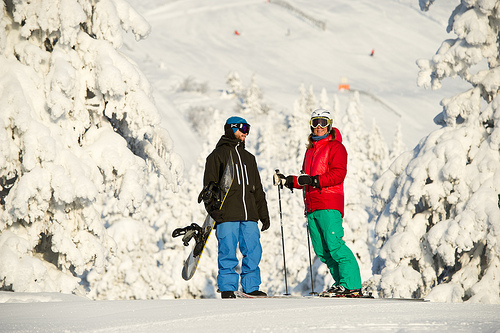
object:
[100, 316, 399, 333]
snow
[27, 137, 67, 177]
snow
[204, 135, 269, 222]
sweater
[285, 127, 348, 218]
coat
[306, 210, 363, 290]
pants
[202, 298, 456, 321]
snow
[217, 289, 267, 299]
boots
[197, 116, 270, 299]
guy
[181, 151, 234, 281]
snowboard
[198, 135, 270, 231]
coat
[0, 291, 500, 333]
ground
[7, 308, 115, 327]
snow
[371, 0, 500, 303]
tree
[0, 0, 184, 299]
tree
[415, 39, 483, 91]
leaves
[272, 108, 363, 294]
man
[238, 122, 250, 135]
goggles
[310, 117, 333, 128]
goggles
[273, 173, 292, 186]
hand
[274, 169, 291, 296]
ski pole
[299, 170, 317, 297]
ski pole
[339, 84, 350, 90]
sign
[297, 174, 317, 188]
glove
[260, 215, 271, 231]
glove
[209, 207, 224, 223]
glove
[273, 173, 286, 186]
glove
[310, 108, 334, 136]
head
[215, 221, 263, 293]
pants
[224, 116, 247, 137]
hat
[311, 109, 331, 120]
hat